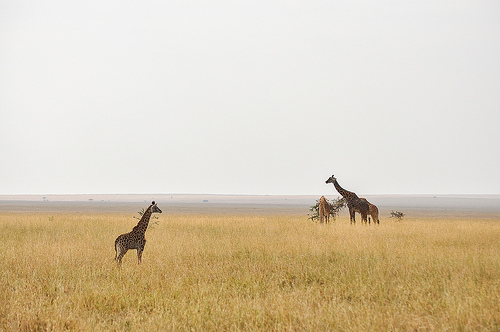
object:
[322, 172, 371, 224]
giraffe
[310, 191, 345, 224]
tree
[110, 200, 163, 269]
baby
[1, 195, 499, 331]
grassland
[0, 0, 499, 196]
sky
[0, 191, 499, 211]
horizon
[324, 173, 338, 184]
head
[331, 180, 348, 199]
neck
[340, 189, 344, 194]
spot